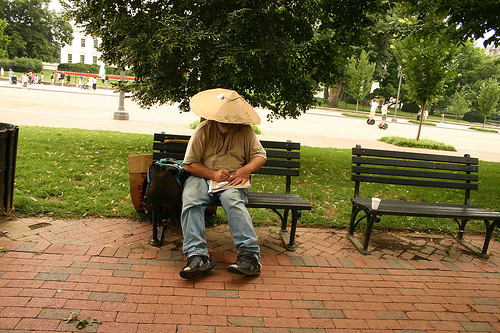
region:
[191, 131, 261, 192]
person has tan shirt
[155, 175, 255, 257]
person has blue pants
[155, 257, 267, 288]
person has black shoes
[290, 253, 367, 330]
red and brown bricks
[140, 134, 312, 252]
person sits on black bench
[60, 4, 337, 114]
green and leafy tree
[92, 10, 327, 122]
tree is behind person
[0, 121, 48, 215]
black trashcan to left of person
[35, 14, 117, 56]
white building in background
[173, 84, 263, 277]
Person sitting on a bench.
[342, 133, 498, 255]
Bench on the walkway.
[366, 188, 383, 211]
White cup on the bench.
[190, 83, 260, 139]
Hat on the person.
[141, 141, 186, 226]
Luggage beside the man.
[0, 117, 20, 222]
Trash can on the walkway.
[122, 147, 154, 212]
Cardboard behind the bench.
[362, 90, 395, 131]
People on segways.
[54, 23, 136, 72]
Building in the background.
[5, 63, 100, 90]
People walking on the sidewalk.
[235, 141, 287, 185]
arm of a person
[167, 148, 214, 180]
arm of a person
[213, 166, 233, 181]
hand of a person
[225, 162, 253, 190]
hand of a person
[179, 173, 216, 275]
leg of a person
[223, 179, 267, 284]
leg of a person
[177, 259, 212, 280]
feet of a person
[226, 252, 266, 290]
feet of a person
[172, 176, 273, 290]
legs of a person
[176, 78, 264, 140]
person wearing a hat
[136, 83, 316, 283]
a man sits on a bench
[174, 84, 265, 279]
man is wearing a conical hat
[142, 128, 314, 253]
large bag on the end of a bench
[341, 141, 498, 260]
a bench has a coffee cup sitting on it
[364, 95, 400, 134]
two people riding segways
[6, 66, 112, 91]
a group of people gathered together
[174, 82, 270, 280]
man is writing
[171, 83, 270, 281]
man is wearing black sandals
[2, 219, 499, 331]
pathway is paved with red bricks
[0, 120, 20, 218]
a trash can next to a pathway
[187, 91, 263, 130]
hat on the man's head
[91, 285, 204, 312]
bricks on the ground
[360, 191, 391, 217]
cup on the bench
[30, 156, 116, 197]
grass on the ground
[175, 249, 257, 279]
shoes on the feet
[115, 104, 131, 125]
bottom of the pole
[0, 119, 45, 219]
side of the trash can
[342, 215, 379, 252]
legs of the bench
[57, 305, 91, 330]
grass in the brick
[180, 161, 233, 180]
arm of the man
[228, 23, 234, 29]
A green leaf on a plant